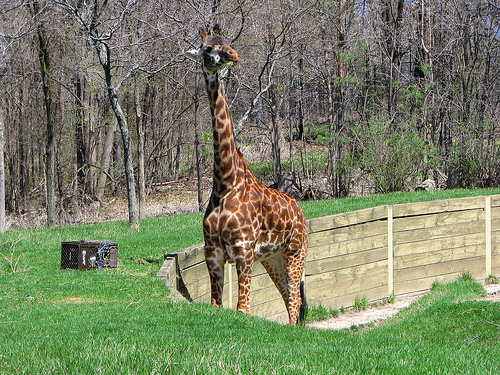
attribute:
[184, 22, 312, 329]
giraffe — adult, standing, eating, brown, tan, yellow, tall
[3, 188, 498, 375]
grass — green, short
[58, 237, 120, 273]
crate — empty, brown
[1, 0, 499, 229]
many trees — leafless, mostly bare, thin, bare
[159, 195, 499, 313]
wall — wooden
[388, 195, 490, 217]
board — brown, unpolished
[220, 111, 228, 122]
spot — brown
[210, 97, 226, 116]
spot — brown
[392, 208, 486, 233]
board — brown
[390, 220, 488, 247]
board — brown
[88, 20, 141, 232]
tree — dead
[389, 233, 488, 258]
board — brown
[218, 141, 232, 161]
spot — brown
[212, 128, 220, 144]
spot — brown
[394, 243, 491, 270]
board — brown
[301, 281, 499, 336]
ground — dirt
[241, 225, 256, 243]
spot — brown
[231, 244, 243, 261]
spot — brown